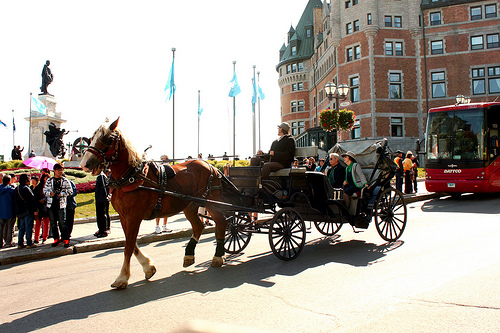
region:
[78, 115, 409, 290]
Horse pulling a carriage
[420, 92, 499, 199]
A red colored bus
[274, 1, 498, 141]
A large brown brick building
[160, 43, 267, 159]
Five blue colored flags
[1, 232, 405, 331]
Shadows on the road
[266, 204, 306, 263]
A round wheel under carriage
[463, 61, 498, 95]
Two windows on the building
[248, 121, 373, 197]
People riding the carriage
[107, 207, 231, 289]
Four legs of a horse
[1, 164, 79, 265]
People standing on the sidewalk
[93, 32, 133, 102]
this is the sky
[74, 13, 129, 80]
the sky has clouds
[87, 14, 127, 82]
the clouds are white in color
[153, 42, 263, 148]
these are some flags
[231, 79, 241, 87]
the flag is blue in color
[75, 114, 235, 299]
this is a horse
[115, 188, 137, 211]
the fur is brown in color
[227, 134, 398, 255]
this is a chariot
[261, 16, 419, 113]
this is a building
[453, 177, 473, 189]
the bus is red in color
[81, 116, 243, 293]
The horse is brown and white.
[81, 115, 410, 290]
The horse is pulling a carriage.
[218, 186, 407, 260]
The carriage has four wheels.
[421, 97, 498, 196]
The bus is red.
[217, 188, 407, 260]
The wheels have spokes.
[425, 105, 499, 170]
The bus has one large front window.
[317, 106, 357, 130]
Flowers hang from the street lamp.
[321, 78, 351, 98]
Two lights are on the street lamp.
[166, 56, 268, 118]
The flags are a very bright blue.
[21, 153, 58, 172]
The umbrella is pink.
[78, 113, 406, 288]
a large horse pulling an open carriage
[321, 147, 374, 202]
two passengers riding in carriage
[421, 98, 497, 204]
red and black bus at curb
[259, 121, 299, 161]
carriage driver is looking off to the side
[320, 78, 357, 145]
two old fashioned style street lamps on a post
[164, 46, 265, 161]
a grouping of blue flags on poles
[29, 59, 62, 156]
statue atop a white pedestal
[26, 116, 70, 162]
statue in front of pedestal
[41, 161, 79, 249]
man standing on curb is wearing red shoes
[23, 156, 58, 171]
a pink umbrella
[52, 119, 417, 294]
people riding in a carriage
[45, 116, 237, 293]
large brown horse walking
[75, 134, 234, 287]
horse walking down the street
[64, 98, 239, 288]
harness on top of horse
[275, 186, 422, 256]
wooden wheels of vehicle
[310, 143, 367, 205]
two people sitting in carraige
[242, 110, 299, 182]
driving of carriage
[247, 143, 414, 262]
black and grey carriage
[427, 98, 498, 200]
large red bus driving on street